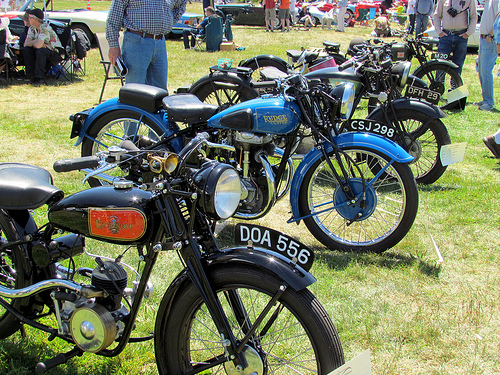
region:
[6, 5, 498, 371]
Several classic bikes are on display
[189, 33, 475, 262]
License plates are on the front fender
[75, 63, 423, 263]
Blue motorcycle has rear and front fenders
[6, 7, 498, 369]
All cycles have spoked wheels on them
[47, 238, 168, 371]
Motorcycle has very small engine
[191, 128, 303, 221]
Motorcycle has chrome footrests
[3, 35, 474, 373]
row of cycles in grass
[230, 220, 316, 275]
black and white identification tag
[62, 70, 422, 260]
blue cycle with black seat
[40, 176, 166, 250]
red and black gas tank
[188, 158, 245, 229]
black cycle head light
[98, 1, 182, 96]
portion of person in checkered shirt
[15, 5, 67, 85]
person sitting in chair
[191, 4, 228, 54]
back of person in chair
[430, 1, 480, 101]
person with hands in pockets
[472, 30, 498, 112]
men's blue denim pants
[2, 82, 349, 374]
black frame bicycle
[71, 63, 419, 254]
blue frame bicycle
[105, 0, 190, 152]
man holding a magazine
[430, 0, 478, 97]
man wearing dark blue jeans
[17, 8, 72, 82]
person sitting on a black chair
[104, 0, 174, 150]
man wearing a plaid shirt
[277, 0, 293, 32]
man wearing an orange shirt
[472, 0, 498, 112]
man wearing light blue jeans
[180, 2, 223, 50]
man sitting on a chair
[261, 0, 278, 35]
man wearing khaki shorts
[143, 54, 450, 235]
Several motorcycles on the grass.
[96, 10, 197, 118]
Man standing behind the motorcycle.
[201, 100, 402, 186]
The motorcycle is blue.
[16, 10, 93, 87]
A person is sitting in the chair.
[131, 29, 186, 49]
The person is wearing a belt.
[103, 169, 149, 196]
Cap of the gas tank.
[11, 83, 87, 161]
The grass is green.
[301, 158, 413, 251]
The wheel of the motorcycle.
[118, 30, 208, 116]
The man is wearing blue jeans.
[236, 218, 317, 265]
the license plat doa556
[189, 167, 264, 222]
The head light on the bike to the far left.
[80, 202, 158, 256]
The red portion of the bike to the left.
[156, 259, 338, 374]
wheel of a motorcycle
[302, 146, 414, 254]
wheel of a motorcycle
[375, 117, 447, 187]
wheel of a motorcycle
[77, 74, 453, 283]
The bike is blue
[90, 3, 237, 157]
The man is wearing jeans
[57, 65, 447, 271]
The bike is parked in the grass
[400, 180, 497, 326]
The grass is brown and green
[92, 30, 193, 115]
The person is holding an object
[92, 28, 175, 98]
the person is wearing a belt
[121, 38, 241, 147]
The seat is black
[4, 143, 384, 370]
The motorcycle to the far left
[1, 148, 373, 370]
A motorcycle to the far left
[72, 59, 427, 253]
A blue motorcycle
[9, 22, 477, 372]
The set of motorcycles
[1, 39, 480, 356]
A set of motorcycles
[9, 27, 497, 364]
The grassy area under the motorcycle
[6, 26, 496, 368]
The grassy meadow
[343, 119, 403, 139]
The license plate on the blue motorcycle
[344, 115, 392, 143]
A license plate on the blue motorcycle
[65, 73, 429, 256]
Blue motorcycle with skinny black tires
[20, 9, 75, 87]
Man with a black cap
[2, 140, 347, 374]
Black motorcycle with bicycle tires